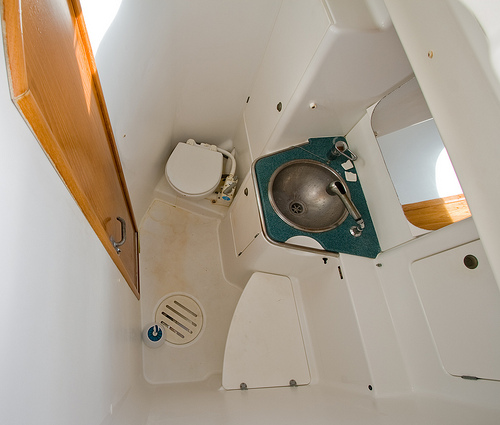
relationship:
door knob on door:
[109, 214, 126, 254] [3, 55, 140, 212]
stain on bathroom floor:
[145, 198, 192, 293] [139, 199, 243, 384]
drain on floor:
[153, 294, 204, 349] [124, 187, 250, 386]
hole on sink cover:
[461, 252, 479, 268] [407, 237, 498, 386]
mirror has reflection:
[370, 73, 462, 229] [434, 147, 471, 224]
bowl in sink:
[269, 157, 359, 235] [253, 136, 380, 263]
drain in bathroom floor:
[155, 295, 203, 345] [136, 227, 214, 307]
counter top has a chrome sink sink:
[255, 134, 380, 257] [253, 136, 380, 263]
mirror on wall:
[370, 73, 462, 229] [342, 110, 436, 251]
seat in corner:
[196, 274, 374, 423] [204, 278, 377, 423]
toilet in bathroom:
[159, 125, 241, 207] [2, 6, 487, 418]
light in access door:
[79, 0, 133, 69] [228, 171, 261, 258]